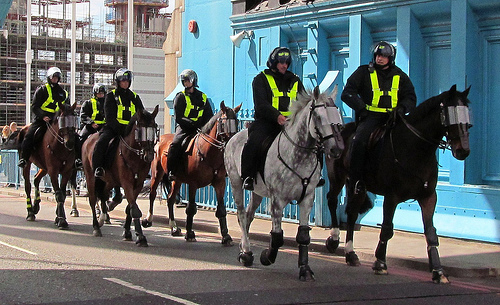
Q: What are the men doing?
A: Riding horses.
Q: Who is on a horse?
A: A man.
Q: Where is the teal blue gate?
A: Next to the horses.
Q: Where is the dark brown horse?
A: In the front.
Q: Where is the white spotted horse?
A: To the left.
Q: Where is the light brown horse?
A: Behind the white horse.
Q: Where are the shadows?
A: On the paved road.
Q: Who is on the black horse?
A: A policeman.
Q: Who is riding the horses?
A: Police.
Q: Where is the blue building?
A: Background.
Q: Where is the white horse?
A: In front.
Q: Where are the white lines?
A: On road.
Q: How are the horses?
A: In row.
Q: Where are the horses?
A: Road.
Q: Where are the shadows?
A: Road.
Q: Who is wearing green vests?
A: The men.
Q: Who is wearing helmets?
A: The men.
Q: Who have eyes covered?
A: The horses.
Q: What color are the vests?
A: Yellow.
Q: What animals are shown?
A: Horses.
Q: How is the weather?
A: Clear.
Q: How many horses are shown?
A: Six.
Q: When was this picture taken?
A: Daytime.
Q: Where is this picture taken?
A: A street.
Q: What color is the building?
A: Blue.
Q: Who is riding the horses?
A: Policemen.